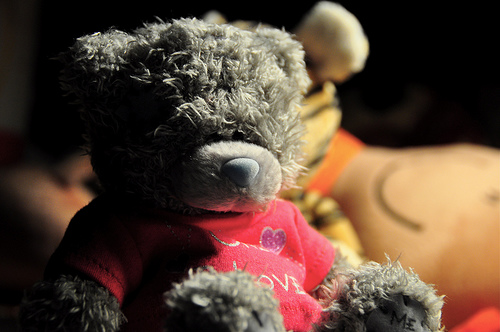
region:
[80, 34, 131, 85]
The left ear of the bear.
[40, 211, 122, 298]
The left arm of the bear.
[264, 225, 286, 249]
The heart on the bear's shirt.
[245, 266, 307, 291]
The letters OVE on the bear's shirt.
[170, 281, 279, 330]
The left foot of the bear.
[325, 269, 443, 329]
The right foot of the bear.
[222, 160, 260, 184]
The bear's nose.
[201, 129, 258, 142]
The eyes of the bear.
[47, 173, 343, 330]
The red t-shirt the bear is wearing.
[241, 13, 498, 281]
The doll behind the bear.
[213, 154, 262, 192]
grey nose on bear's face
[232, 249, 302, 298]
word love written in white letters on red shirt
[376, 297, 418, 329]
word "me" on bear's foot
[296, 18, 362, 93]
another stuffed animal's ear behind bear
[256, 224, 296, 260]
light pink heart on bear's shirt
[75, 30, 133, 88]
grey bear's ear on left of photo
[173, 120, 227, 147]
small black eye on bear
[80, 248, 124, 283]
dark stitching on bears sleeve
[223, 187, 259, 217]
grey stitching for mouth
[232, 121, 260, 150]
dark eye on bear in photo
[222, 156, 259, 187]
gray nose on teddybear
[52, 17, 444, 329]
teddybear is gray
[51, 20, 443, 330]
teddybear wearing red shirt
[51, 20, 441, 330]
toy in front of other toys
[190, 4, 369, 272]
toy in front of other toys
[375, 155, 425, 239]
smile on plush toy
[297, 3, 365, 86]
white ear on plush toy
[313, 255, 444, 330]
brown paw on teddybear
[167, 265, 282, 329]
brown paw on teddybear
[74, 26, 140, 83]
gray ear on teddybear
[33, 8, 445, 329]
a gray teddy bear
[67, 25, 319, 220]
the head of a teddy bear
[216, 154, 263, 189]
the nose of a teddy bear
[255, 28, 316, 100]
the ear of a teddy bear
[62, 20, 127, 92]
the ear of a teddy bear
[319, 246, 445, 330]
the arm of a teddy bear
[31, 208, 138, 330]
the arm of a teddy bear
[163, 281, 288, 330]
the foot of a teddy bear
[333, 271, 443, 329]
the foot of a teddy bear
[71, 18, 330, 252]
the teddy bear is gray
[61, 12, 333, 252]
a gray teddy bear